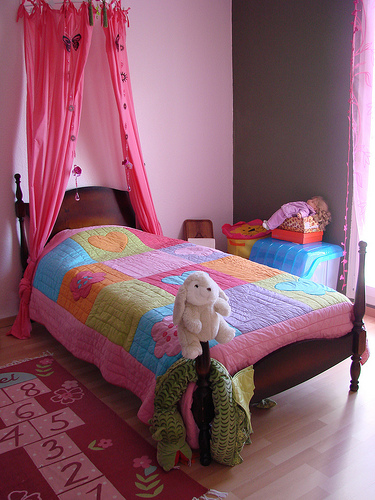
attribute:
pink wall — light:
[233, 1, 374, 306]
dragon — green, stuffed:
[149, 358, 251, 468]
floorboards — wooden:
[176, 315, 373, 499]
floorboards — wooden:
[1, 324, 157, 447]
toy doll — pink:
[260, 191, 333, 233]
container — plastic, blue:
[246, 234, 343, 292]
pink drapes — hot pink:
[340, 8, 373, 106]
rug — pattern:
[6, 350, 205, 492]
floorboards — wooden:
[225, 408, 342, 498]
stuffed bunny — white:
[172, 270, 235, 357]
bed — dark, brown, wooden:
[40, 167, 374, 449]